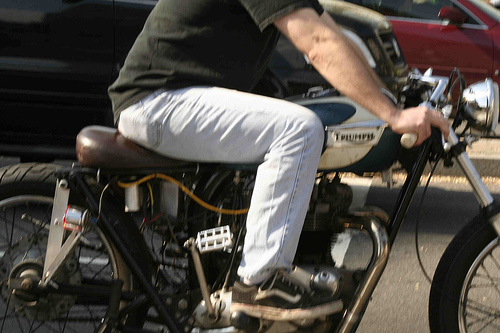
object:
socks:
[238, 270, 278, 288]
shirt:
[108, 0, 324, 123]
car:
[341, 0, 500, 120]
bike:
[0, 67, 497, 333]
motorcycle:
[0, 66, 500, 333]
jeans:
[116, 83, 326, 285]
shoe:
[226, 264, 343, 321]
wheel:
[427, 198, 500, 333]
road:
[0, 133, 499, 333]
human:
[106, 0, 450, 323]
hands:
[389, 101, 449, 146]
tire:
[1, 161, 151, 333]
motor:
[118, 179, 185, 218]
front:
[322, 0, 411, 96]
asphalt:
[363, 179, 485, 331]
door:
[0, 1, 169, 147]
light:
[460, 77, 500, 134]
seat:
[74, 126, 189, 169]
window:
[381, 0, 488, 29]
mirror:
[438, 6, 466, 24]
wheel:
[395, 69, 447, 111]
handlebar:
[398, 75, 455, 148]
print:
[334, 129, 376, 146]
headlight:
[462, 80, 498, 135]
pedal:
[194, 224, 235, 255]